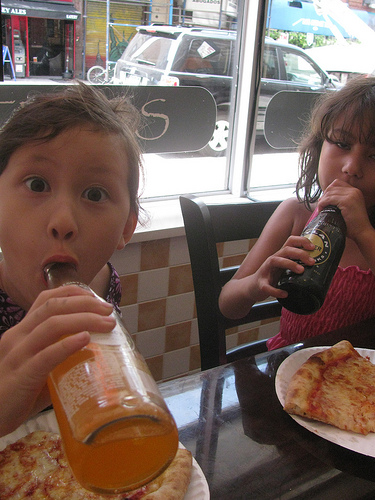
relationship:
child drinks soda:
[0, 77, 152, 443] [40, 258, 178, 493]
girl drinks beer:
[221, 74, 373, 359] [275, 206, 353, 317]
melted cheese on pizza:
[327, 381, 360, 419] [283, 336, 374, 438]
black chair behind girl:
[178, 193, 295, 373] [215, 71, 373, 329]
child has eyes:
[6, 89, 158, 320] [17, 159, 122, 204]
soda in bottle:
[54, 333, 185, 494] [42, 275, 184, 444]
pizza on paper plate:
[284, 333, 374, 449] [272, 345, 375, 463]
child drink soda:
[0, 77, 152, 443] [49, 330, 185, 494]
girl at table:
[218, 74, 375, 358] [1, 322, 374, 497]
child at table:
[0, 77, 152, 443] [1, 322, 374, 497]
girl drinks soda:
[218, 74, 375, 358] [275, 199, 346, 315]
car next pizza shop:
[108, 22, 345, 157] [3, 6, 373, 491]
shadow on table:
[234, 366, 282, 442] [131, 333, 373, 494]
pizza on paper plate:
[283, 333, 374, 456] [272, 345, 362, 456]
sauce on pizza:
[112, 474, 150, 498] [283, 336, 374, 438]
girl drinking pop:
[218, 74, 375, 358] [24, 253, 186, 480]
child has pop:
[0, 77, 152, 443] [28, 244, 182, 494]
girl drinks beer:
[218, 74, 375, 358] [283, 197, 357, 317]